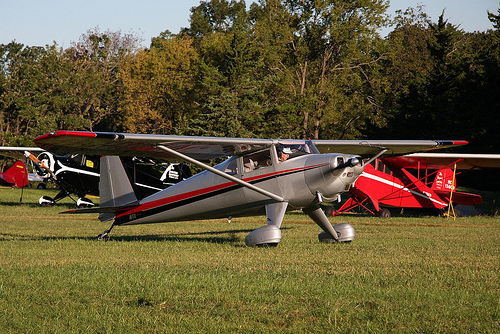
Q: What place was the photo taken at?
A: It was taken at the field.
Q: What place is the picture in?
A: It is at the field.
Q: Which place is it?
A: It is a field.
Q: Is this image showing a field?
A: Yes, it is showing a field.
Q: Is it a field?
A: Yes, it is a field.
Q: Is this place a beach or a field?
A: It is a field.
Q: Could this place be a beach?
A: No, it is a field.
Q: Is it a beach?
A: No, it is a field.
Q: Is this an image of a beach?
A: No, the picture is showing a field.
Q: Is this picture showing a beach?
A: No, the picture is showing a field.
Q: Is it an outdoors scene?
A: Yes, it is outdoors.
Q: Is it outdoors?
A: Yes, it is outdoors.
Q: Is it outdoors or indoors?
A: It is outdoors.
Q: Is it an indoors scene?
A: No, it is outdoors.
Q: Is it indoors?
A: No, it is outdoors.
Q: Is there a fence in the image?
A: No, there are no fences.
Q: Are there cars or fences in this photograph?
A: No, there are no fences or cars.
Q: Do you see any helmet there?
A: No, there are no helmets.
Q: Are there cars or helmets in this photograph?
A: No, there are no helmets or cars.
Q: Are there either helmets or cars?
A: No, there are no helmets or cars.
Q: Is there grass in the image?
A: Yes, there is grass.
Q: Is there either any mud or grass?
A: Yes, there is grass.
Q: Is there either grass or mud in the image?
A: Yes, there is grass.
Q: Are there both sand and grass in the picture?
A: No, there is grass but no sand.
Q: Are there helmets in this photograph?
A: No, there are no helmets.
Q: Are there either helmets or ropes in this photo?
A: No, there are no helmets or ropes.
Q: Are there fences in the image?
A: No, there are no fences.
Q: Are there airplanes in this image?
A: Yes, there is an airplane.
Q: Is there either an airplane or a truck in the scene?
A: Yes, there is an airplane.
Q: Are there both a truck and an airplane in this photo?
A: No, there is an airplane but no trucks.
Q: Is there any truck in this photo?
A: No, there are no trucks.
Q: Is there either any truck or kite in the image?
A: No, there are no trucks or kites.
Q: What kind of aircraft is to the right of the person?
A: The aircraft is an airplane.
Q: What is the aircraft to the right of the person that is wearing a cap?
A: The aircraft is an airplane.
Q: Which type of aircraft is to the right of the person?
A: The aircraft is an airplane.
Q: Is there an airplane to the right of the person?
A: Yes, there is an airplane to the right of the person.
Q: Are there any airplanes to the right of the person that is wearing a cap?
A: Yes, there is an airplane to the right of the person.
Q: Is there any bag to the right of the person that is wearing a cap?
A: No, there is an airplane to the right of the person.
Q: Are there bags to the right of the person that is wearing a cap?
A: No, there is an airplane to the right of the person.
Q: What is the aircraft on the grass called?
A: The aircraft is an airplane.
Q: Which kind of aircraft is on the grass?
A: The aircraft is an airplane.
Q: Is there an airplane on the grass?
A: Yes, there is an airplane on the grass.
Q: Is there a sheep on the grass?
A: No, there is an airplane on the grass.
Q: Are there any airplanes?
A: Yes, there is an airplane.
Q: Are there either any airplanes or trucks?
A: Yes, there is an airplane.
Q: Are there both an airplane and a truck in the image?
A: No, there is an airplane but no trucks.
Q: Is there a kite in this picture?
A: No, there are no kites.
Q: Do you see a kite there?
A: No, there are no kites.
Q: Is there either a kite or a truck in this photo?
A: No, there are no kites or trucks.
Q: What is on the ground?
A: The airplane is on the ground.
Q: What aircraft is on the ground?
A: The aircraft is an airplane.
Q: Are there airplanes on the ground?
A: Yes, there is an airplane on the ground.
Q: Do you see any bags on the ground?
A: No, there is an airplane on the ground.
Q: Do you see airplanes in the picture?
A: Yes, there is an airplane.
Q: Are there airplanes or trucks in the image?
A: Yes, there is an airplane.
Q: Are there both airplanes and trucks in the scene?
A: No, there is an airplane but no trucks.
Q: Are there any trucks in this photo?
A: No, there are no trucks.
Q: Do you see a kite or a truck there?
A: No, there are no trucks or kites.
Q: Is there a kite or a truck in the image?
A: No, there are no trucks or kites.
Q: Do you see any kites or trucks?
A: No, there are no trucks or kites.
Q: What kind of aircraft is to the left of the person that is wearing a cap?
A: The aircraft is an airplane.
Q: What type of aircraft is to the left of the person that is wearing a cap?
A: The aircraft is an airplane.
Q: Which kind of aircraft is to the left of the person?
A: The aircraft is an airplane.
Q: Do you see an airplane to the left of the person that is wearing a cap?
A: Yes, there is an airplane to the left of the person.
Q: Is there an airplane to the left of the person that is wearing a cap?
A: Yes, there is an airplane to the left of the person.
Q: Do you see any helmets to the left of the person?
A: No, there is an airplane to the left of the person.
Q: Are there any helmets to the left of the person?
A: No, there is an airplane to the left of the person.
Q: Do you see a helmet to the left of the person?
A: No, there is an airplane to the left of the person.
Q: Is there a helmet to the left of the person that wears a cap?
A: No, there is an airplane to the left of the person.